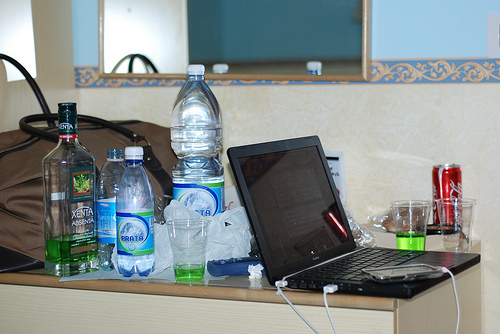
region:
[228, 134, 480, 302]
black laptop computer at edge of table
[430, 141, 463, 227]
soda can near a wall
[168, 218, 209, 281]
clear plastic cup with small amount of green liquid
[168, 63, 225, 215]
large water bottle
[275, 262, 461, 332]
electronic device connected to computer through white cord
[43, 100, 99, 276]
liquor bottle with green liquid inside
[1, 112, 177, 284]
large brown and black bag on table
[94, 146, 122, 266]
an uncapped water bottle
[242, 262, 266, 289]
crumpled piece of paper on table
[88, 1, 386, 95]
bottom section of a mirror on wall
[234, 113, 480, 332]
a laptop stands ready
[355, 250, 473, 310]
the phone is on a charger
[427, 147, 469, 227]
a coke can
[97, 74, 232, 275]
water bottles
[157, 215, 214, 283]
a green glass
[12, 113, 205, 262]
a brown duffle bag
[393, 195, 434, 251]
a half full glass of something green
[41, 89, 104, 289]
it appears this is a bottle of liquor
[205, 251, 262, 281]
a remote controller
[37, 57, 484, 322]
the area is quite messy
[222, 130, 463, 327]
the laptop is open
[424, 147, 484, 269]
a red soda can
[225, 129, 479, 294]
laptop on a counter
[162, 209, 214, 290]
cup on a counter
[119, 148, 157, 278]
bottle on the counter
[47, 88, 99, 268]
bottle on the counter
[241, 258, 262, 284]
garbage on the counter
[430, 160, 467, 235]
soda can on the counter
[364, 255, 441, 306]
phone charging on a computer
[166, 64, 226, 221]
bottle on the counter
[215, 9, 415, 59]
mirror behind counter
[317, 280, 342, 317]
plug in computer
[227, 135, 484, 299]
black computer on the counter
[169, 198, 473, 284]
plastic cups near computer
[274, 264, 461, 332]
white cord connected to computer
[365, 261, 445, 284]
cell phone connected to computer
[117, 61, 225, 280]
bottles of water on the counter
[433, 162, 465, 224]
Coca-Cola can near the computer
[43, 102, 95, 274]
bottle with green liquid on the counter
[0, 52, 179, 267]
brown duffle bag on the counter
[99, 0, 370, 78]
mirror on the wall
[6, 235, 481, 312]
a cluttered counter top